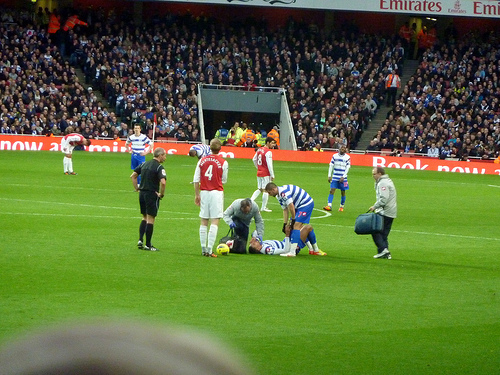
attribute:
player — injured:
[123, 145, 196, 251]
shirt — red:
[179, 133, 231, 191]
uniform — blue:
[126, 135, 149, 168]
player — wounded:
[243, 225, 325, 261]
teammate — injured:
[246, 225, 327, 256]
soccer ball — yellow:
[212, 244, 234, 259]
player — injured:
[242, 217, 329, 260]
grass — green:
[23, 267, 490, 367]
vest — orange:
[381, 73, 408, 88]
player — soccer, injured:
[244, 225, 327, 264]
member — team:
[215, 187, 272, 259]